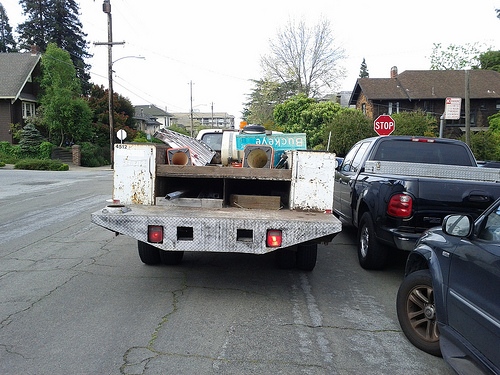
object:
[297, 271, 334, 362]
lines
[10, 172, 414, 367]
street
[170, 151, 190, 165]
cones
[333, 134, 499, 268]
pickup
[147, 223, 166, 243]
tail lights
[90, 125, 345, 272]
truck